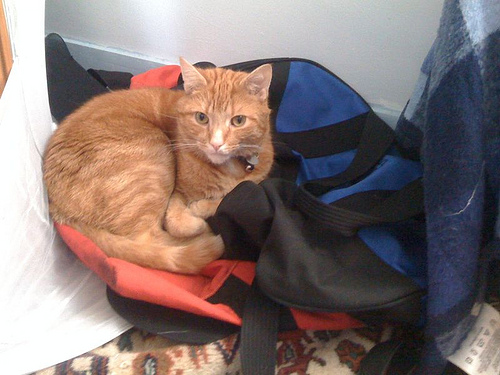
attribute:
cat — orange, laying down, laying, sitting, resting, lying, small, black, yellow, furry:
[41, 56, 274, 279]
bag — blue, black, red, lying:
[219, 58, 427, 336]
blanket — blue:
[395, 1, 499, 372]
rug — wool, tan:
[28, 326, 392, 375]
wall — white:
[47, 2, 443, 112]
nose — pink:
[212, 134, 224, 147]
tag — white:
[447, 301, 499, 375]